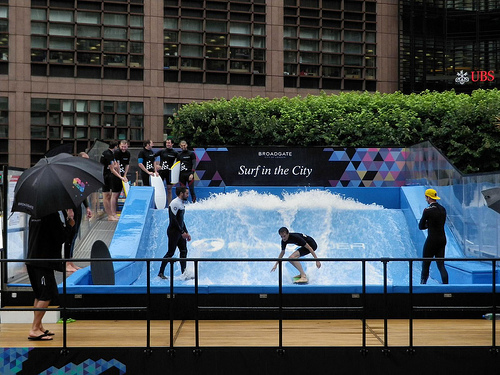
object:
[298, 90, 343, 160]
person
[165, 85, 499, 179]
bushes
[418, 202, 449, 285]
wetsuit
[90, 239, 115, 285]
board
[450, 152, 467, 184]
ground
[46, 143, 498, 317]
surf area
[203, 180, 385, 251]
wave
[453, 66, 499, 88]
sign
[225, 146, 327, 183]
sign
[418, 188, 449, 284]
man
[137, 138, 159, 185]
person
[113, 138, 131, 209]
person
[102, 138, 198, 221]
group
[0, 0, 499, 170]
building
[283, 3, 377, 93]
windows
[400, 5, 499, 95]
windows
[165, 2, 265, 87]
windows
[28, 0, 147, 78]
windows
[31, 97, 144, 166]
windows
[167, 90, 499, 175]
tree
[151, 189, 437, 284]
surf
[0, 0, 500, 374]
city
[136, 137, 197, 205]
people waiting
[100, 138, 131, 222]
people waiting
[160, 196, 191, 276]
wet suit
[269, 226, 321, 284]
man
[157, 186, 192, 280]
man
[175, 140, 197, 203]
man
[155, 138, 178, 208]
man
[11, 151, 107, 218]
umbrella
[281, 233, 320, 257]
wetsuit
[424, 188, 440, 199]
cap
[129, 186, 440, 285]
water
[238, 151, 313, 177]
lettering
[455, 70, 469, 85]
logo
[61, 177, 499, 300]
pool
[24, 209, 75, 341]
person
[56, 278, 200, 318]
pool edge